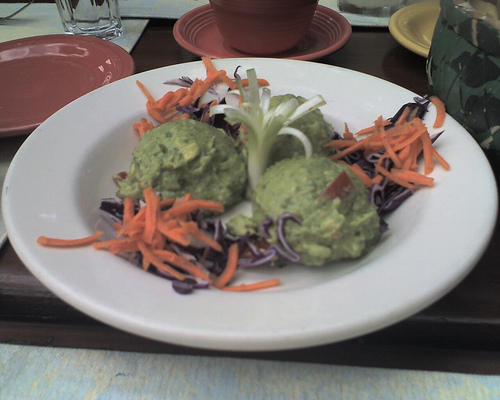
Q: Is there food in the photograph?
A: Yes, there is food.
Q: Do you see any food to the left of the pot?
A: Yes, there is food to the left of the pot.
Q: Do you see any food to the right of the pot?
A: No, the food is to the left of the pot.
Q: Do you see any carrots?
A: Yes, there are carrots.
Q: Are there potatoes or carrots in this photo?
A: Yes, there are carrots.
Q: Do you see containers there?
A: No, there are no containers.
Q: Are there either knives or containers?
A: No, there are no containers or knives.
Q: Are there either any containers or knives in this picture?
A: No, there are no containers or knives.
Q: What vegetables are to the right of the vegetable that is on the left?
A: The vegetables are carrots.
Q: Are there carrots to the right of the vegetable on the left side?
A: Yes, there are carrots to the right of the vegetable.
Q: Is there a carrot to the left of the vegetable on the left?
A: No, the carrots are to the right of the vegetable.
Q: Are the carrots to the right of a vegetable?
A: Yes, the carrots are to the right of a vegetable.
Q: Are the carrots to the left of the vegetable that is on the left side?
A: No, the carrots are to the right of the vegetable.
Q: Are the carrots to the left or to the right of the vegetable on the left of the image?
A: The carrots are to the right of the vegetable.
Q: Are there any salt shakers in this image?
A: No, there are no salt shakers.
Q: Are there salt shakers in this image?
A: No, there are no salt shakers.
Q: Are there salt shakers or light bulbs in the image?
A: No, there are no salt shakers or light bulbs.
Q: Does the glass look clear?
A: Yes, the glass is clear.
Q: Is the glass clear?
A: Yes, the glass is clear.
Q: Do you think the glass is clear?
A: Yes, the glass is clear.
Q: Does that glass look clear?
A: Yes, the glass is clear.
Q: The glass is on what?
A: The glass is on the table.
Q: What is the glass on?
A: The glass is on the table.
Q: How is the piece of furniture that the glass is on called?
A: The piece of furniture is a table.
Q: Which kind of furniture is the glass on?
A: The glass is on the table.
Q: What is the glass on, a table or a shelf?
A: The glass is on a table.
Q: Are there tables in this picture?
A: Yes, there is a table.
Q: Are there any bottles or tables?
A: Yes, there is a table.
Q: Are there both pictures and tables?
A: No, there is a table but no pictures.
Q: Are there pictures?
A: No, there are no pictures.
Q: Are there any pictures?
A: No, there are no pictures.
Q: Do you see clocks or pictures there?
A: No, there are no pictures or clocks.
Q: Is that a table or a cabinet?
A: That is a table.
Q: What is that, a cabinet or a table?
A: That is a table.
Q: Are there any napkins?
A: No, there are no napkins.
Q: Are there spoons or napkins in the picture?
A: No, there are no napkins or spoons.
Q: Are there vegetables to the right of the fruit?
A: Yes, there is a vegetable to the right of the fruit.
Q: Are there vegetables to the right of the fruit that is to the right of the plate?
A: Yes, there is a vegetable to the right of the fruit.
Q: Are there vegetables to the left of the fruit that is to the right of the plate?
A: No, the vegetable is to the right of the fruit.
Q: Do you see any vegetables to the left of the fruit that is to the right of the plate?
A: No, the vegetable is to the right of the fruit.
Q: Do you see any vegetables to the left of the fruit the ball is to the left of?
A: No, the vegetable is to the right of the fruit.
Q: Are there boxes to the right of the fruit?
A: No, there is a vegetable to the right of the fruit.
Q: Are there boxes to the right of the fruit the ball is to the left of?
A: No, there is a vegetable to the right of the fruit.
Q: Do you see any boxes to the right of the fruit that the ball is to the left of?
A: No, there is a vegetable to the right of the fruit.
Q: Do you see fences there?
A: No, there are no fences.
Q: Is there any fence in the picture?
A: No, there are no fences.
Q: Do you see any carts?
A: No, there are no carts.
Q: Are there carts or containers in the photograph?
A: No, there are no carts or containers.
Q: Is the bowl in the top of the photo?
A: Yes, the bowl is in the top of the image.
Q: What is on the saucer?
A: The bowl is on the saucer.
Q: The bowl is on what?
A: The bowl is on the saucer.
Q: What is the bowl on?
A: The bowl is on the saucer.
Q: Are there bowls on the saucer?
A: Yes, there is a bowl on the saucer.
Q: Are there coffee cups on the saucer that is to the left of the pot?
A: No, there is a bowl on the saucer.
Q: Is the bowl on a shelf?
A: No, the bowl is on a saucer.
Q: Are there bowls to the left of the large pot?
A: Yes, there is a bowl to the left of the pot.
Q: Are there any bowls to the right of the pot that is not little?
A: No, the bowl is to the left of the pot.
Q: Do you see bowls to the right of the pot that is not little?
A: No, the bowl is to the left of the pot.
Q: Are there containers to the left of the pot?
A: No, there is a bowl to the left of the pot.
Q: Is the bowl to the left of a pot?
A: Yes, the bowl is to the left of a pot.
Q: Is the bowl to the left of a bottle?
A: No, the bowl is to the left of a pot.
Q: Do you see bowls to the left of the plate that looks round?
A: Yes, there is a bowl to the left of the plate.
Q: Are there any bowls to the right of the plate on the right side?
A: No, the bowl is to the left of the plate.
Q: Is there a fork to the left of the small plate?
A: No, there is a bowl to the left of the plate.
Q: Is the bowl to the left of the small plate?
A: Yes, the bowl is to the left of the plate.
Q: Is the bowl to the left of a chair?
A: No, the bowl is to the left of the plate.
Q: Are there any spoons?
A: No, there are no spoons.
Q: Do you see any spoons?
A: No, there are no spoons.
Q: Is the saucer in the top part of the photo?
A: Yes, the saucer is in the top of the image.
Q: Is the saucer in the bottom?
A: No, the saucer is in the top of the image.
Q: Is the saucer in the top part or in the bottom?
A: The saucer is in the top of the image.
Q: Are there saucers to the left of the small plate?
A: Yes, there is a saucer to the left of the plate.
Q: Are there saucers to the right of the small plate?
A: No, the saucer is to the left of the plate.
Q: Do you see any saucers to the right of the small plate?
A: No, the saucer is to the left of the plate.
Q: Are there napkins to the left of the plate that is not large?
A: No, there is a saucer to the left of the plate.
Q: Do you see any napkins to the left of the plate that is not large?
A: No, there is a saucer to the left of the plate.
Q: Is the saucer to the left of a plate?
A: Yes, the saucer is to the left of a plate.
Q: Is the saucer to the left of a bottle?
A: No, the saucer is to the left of a plate.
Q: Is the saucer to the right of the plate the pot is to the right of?
A: No, the saucer is to the left of the plate.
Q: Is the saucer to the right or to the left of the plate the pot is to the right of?
A: The saucer is to the left of the plate.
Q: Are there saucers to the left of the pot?
A: Yes, there is a saucer to the left of the pot.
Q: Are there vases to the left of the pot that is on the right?
A: No, there is a saucer to the left of the pot.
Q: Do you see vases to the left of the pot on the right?
A: No, there is a saucer to the left of the pot.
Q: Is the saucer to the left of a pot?
A: Yes, the saucer is to the left of a pot.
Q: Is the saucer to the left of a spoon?
A: No, the saucer is to the left of a pot.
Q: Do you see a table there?
A: Yes, there is a table.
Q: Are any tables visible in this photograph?
A: Yes, there is a table.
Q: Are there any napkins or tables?
A: Yes, there is a table.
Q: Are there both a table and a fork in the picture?
A: No, there is a table but no forks.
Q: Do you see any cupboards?
A: No, there are no cupboards.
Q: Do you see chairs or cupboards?
A: No, there are no cupboards or chairs.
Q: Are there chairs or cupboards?
A: No, there are no cupboards or chairs.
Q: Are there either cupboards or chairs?
A: No, there are no cupboards or chairs.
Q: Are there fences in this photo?
A: No, there are no fences.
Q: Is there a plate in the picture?
A: Yes, there is a plate.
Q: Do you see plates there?
A: Yes, there is a plate.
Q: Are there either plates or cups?
A: Yes, there is a plate.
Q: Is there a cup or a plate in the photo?
A: Yes, there is a plate.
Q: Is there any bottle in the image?
A: No, there are no bottles.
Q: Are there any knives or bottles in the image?
A: No, there are no bottles or knives.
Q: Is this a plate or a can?
A: This is a plate.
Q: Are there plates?
A: Yes, there is a plate.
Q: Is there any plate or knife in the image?
A: Yes, there is a plate.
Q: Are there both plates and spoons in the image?
A: No, there is a plate but no spoons.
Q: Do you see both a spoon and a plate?
A: No, there is a plate but no spoons.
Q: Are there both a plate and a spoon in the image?
A: No, there is a plate but no spoons.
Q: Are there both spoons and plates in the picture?
A: No, there is a plate but no spoons.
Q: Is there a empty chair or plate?
A: Yes, there is an empty plate.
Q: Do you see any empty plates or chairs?
A: Yes, there is an empty plate.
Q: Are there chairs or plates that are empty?
A: Yes, the plate is empty.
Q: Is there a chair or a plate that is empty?
A: Yes, the plate is empty.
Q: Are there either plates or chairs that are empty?
A: Yes, the plate is empty.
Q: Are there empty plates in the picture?
A: Yes, there is an empty plate.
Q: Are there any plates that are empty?
A: Yes, there is a plate that is empty.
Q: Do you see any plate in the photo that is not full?
A: Yes, there is a empty plate.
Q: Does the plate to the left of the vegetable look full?
A: No, the plate is empty.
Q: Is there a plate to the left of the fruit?
A: Yes, there is a plate to the left of the fruit.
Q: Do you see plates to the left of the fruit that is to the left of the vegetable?
A: Yes, there is a plate to the left of the fruit.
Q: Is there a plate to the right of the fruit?
A: No, the plate is to the left of the fruit.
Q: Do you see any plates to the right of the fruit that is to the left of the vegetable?
A: No, the plate is to the left of the fruit.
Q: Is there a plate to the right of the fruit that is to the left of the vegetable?
A: No, the plate is to the left of the fruit.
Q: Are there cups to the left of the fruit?
A: No, there is a plate to the left of the fruit.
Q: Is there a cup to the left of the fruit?
A: No, there is a plate to the left of the fruit.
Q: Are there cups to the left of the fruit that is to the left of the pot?
A: No, there is a plate to the left of the fruit.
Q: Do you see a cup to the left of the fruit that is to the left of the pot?
A: No, there is a plate to the left of the fruit.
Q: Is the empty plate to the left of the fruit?
A: Yes, the plate is to the left of the fruit.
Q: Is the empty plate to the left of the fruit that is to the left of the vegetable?
A: Yes, the plate is to the left of the fruit.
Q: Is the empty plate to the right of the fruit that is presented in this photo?
A: No, the plate is to the left of the fruit.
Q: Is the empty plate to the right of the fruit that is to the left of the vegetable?
A: No, the plate is to the left of the fruit.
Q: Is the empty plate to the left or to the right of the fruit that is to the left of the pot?
A: The plate is to the left of the fruit.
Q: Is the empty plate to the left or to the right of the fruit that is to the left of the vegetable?
A: The plate is to the left of the fruit.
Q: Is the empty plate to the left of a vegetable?
A: Yes, the plate is to the left of a vegetable.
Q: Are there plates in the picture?
A: Yes, there is a plate.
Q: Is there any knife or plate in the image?
A: Yes, there is a plate.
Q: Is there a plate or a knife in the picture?
A: Yes, there is a plate.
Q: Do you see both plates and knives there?
A: No, there is a plate but no knives.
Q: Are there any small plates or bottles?
A: Yes, there is a small plate.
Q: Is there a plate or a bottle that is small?
A: Yes, the plate is small.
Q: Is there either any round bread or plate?
A: Yes, there is a round plate.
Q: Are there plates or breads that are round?
A: Yes, the plate is round.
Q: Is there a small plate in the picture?
A: Yes, there is a small plate.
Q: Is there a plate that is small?
A: Yes, there is a plate that is small.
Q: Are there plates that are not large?
A: Yes, there is a small plate.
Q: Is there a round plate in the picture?
A: Yes, there is a round plate.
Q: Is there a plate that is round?
A: Yes, there is a plate that is round.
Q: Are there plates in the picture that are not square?
A: Yes, there is a round plate.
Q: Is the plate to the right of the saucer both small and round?
A: Yes, the plate is small and round.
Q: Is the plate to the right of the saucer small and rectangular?
A: No, the plate is small but round.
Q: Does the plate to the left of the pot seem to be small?
A: Yes, the plate is small.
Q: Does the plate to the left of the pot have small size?
A: Yes, the plate is small.